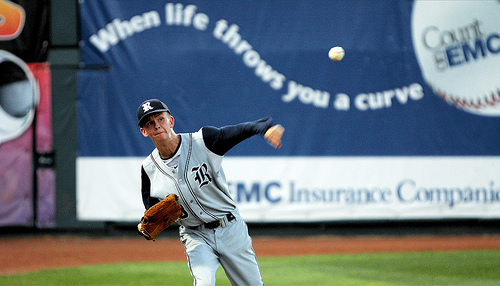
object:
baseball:
[328, 46, 346, 62]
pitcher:
[135, 98, 284, 286]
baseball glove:
[135, 194, 183, 241]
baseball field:
[0, 223, 498, 285]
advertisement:
[77, 0, 499, 222]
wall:
[0, 0, 499, 235]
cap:
[135, 99, 172, 127]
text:
[86, 2, 425, 112]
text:
[423, 19, 499, 71]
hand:
[263, 124, 286, 150]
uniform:
[139, 117, 278, 286]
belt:
[190, 213, 235, 230]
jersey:
[140, 117, 277, 228]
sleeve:
[200, 116, 272, 156]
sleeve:
[140, 163, 160, 210]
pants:
[178, 213, 265, 286]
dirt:
[0, 233, 120, 264]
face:
[139, 111, 174, 141]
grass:
[1, 249, 498, 286]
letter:
[191, 162, 213, 188]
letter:
[142, 101, 154, 113]